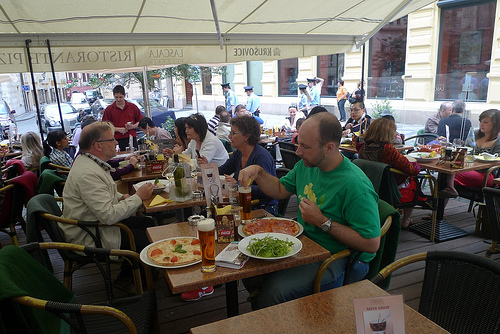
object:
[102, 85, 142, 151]
man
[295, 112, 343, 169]
head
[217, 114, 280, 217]
woman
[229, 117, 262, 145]
curly hair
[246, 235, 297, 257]
salad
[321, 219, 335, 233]
watch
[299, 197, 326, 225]
hand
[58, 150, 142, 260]
shirt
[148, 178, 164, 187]
food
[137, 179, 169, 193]
bowl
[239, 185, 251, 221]
beer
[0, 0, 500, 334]
table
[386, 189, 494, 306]
ground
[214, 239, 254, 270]
book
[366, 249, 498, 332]
chair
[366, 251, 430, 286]
cane arms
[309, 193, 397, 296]
chair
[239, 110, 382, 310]
man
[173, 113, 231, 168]
woman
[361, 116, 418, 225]
woman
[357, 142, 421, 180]
red shirt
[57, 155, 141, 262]
jacket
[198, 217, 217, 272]
glass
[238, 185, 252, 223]
glass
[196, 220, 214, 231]
foam head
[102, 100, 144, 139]
shirt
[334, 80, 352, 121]
lady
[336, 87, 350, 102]
shirt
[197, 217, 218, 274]
beer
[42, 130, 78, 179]
woman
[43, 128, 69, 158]
hair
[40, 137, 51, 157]
ponytail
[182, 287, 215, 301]
shoe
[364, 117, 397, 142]
hair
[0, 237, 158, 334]
chair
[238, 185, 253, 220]
drinks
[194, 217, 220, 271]
drinks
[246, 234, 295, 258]
vegetables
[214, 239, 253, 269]
menu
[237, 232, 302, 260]
plate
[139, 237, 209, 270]
plate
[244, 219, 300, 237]
food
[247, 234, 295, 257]
food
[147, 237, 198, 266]
food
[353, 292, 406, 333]
menu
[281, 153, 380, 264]
shirt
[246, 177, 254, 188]
lemon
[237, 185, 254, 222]
drink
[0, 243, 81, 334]
jacket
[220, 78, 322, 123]
police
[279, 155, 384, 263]
shirt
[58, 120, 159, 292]
man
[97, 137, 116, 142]
glasses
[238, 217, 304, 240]
plate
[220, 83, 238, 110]
officer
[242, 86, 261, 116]
officer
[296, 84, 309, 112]
officer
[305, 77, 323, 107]
officer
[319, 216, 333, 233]
wrist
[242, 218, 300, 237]
pizza